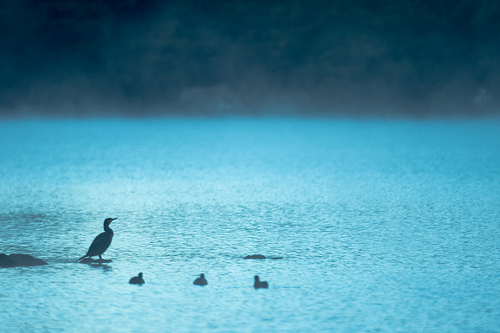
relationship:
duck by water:
[70, 205, 129, 291] [226, 175, 422, 243]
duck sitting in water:
[70, 205, 129, 291] [226, 175, 422, 243]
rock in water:
[4, 238, 48, 303] [226, 175, 422, 243]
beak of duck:
[110, 214, 120, 231] [70, 205, 129, 291]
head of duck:
[104, 211, 117, 230] [70, 205, 129, 291]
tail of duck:
[73, 249, 98, 270] [70, 205, 129, 291]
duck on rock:
[70, 205, 129, 291] [4, 238, 48, 303]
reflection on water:
[99, 178, 277, 210] [226, 175, 422, 243]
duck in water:
[70, 205, 129, 291] [226, 175, 422, 243]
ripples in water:
[391, 172, 435, 194] [226, 175, 422, 243]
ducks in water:
[78, 211, 307, 313] [226, 175, 422, 243]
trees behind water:
[251, 26, 441, 90] [226, 175, 422, 243]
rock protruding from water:
[4, 238, 48, 303] [226, 175, 422, 243]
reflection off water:
[99, 178, 277, 210] [226, 175, 422, 243]